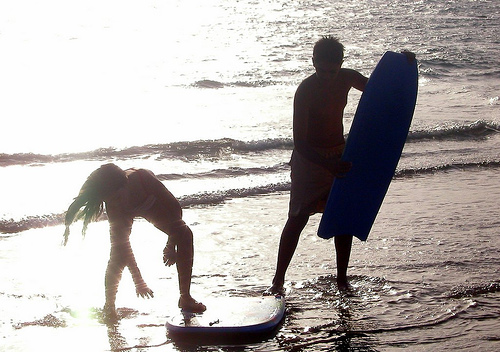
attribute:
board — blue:
[313, 47, 421, 247]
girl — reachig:
[58, 158, 214, 327]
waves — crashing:
[0, 113, 497, 240]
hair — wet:
[60, 160, 130, 247]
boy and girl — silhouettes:
[54, 33, 383, 327]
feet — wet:
[269, 275, 363, 304]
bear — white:
[51, 17, 108, 68]